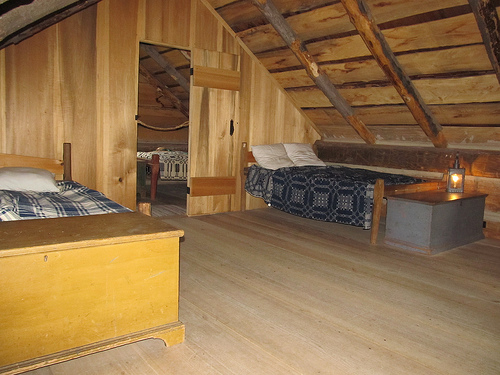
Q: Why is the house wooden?
A: To keep warm.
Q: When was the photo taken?
A: Day time.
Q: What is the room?
A: Beds.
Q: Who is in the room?
A: No one.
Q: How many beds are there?
A: 2.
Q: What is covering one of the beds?
A: Blanket.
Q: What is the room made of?
A: Wood.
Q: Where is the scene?
A: In a bedroom.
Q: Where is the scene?
A: Attic.